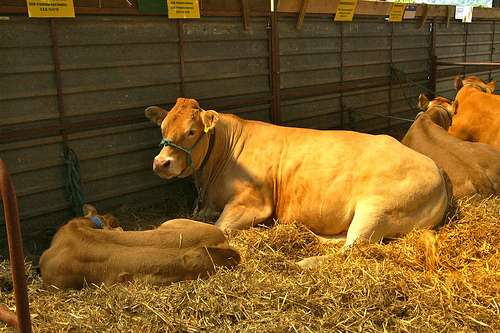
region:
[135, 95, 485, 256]
the cow is sitting on hay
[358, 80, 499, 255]
the cow is sitting on hay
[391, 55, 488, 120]
the cow is sitting on hay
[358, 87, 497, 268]
the cow is tied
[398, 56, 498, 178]
the cow is tied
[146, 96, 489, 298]
the cow is tied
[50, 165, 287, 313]
the cow is tied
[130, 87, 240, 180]
the face of a cow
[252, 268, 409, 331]
straw in a barn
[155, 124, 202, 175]
a harness around the mouth of a cow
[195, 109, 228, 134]
the ear of a cow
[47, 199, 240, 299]
a dark brown cow lying down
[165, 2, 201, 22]
a sign above the cow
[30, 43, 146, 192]
the wooden wall to the stall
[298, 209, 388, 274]
the hind leg of a cow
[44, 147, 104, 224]
a rope holding a cow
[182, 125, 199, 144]
the eye of a cow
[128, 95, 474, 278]
THIS IS A COW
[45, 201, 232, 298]
THIS IS A CALF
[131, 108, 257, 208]
THIS IS A ROPE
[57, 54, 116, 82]
THIS IS A WALL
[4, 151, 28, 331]
THIS IS A PIPE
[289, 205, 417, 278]
THIS IS A LEG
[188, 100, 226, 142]
THIS IS AN EAR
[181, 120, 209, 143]
THIS IS AN EYE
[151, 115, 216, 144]
THESE ARE COW EYES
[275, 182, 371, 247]
THIS IS A BELLY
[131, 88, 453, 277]
cow lying on straw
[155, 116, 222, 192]
green cord harness on cow's head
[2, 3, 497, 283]
grey and brown metal wall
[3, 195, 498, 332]
pile of yellow straw on ground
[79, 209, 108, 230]
blue collar on calf's neck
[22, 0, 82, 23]
green and white laminated sign above cows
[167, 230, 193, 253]
piece of yellow straw on cow's back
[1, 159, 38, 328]
metal rust covered fencing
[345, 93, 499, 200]
tan cow attached to metal wall wiith green rope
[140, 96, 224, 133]
two cow ears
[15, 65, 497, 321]
Four cows laying in hay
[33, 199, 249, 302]
Cow wearing a blue collar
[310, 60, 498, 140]
Two cows tied by blue rope to wall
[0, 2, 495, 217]
Yellow signs along a wall near cows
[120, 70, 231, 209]
Cow with blue rope around its mouth and face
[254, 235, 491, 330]
Pile of hay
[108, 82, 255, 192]
Cow looking to the left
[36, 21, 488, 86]
Long metal wall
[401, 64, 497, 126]
Back of two cows heads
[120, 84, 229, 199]
Cute brown cow